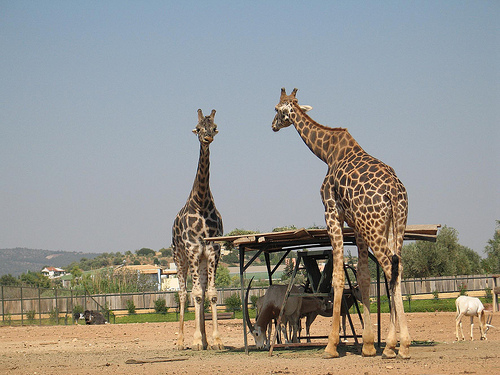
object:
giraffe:
[170, 106, 224, 353]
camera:
[0, 1, 492, 363]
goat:
[450, 293, 494, 340]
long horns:
[485, 314, 496, 325]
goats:
[306, 278, 362, 332]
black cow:
[84, 307, 108, 325]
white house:
[39, 266, 68, 280]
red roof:
[42, 265, 64, 274]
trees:
[2, 273, 11, 286]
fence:
[10, 287, 196, 327]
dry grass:
[216, 340, 338, 358]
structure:
[211, 209, 457, 373]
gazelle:
[452, 293, 494, 341]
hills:
[0, 238, 53, 268]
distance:
[6, 243, 177, 309]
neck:
[289, 116, 366, 164]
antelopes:
[249, 287, 311, 344]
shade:
[210, 202, 468, 272]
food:
[472, 322, 500, 366]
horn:
[233, 271, 264, 336]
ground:
[9, 319, 168, 374]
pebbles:
[36, 343, 49, 345]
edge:
[20, 246, 488, 267]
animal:
[77, 309, 105, 325]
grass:
[3, 293, 500, 316]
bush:
[28, 303, 110, 323]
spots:
[188, 216, 197, 227]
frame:
[229, 238, 270, 353]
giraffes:
[272, 79, 404, 360]